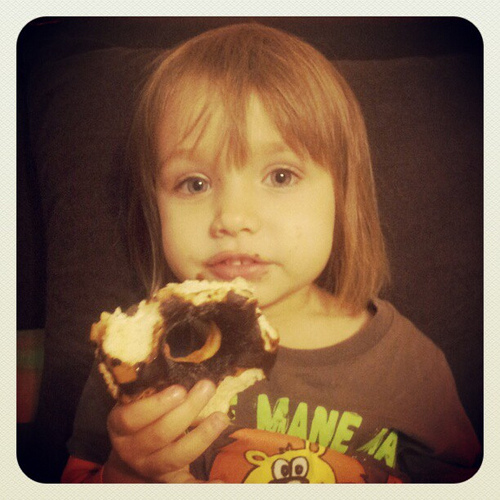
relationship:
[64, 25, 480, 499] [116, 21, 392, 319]
girl with hair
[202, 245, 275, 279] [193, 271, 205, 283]
mouth with crumbs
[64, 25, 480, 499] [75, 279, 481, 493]
girl wearing pullover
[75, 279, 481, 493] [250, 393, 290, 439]
pullover with m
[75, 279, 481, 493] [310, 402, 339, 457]
pullover with n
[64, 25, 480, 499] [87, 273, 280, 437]
girl holding donut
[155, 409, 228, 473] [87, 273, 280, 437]
fingers holding donut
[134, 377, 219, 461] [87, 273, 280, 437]
fingers holding donut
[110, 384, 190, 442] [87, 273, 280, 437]
fingers holding donut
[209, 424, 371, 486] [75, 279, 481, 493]
lion on pullover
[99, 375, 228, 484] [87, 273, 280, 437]
hand holding donut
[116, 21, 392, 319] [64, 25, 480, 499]
hair on girl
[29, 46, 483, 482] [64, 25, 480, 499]
chair behind girl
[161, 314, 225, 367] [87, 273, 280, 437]
center of donut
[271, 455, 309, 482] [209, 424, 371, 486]
eyes of lion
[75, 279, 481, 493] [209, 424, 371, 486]
pullover with lion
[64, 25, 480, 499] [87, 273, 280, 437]
girl eating donut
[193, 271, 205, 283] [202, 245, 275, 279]
crumbs on mouth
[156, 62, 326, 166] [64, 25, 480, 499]
bangs on girl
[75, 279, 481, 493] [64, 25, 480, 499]
pullover of girl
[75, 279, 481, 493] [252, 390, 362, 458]
pullover says mane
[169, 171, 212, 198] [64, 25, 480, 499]
eyes of girl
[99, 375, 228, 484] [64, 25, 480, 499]
hand of girl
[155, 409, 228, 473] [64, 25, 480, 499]
fingers of girl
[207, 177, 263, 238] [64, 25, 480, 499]
nose of girl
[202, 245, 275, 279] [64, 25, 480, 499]
mouth of girl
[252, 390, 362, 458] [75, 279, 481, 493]
mane on pullover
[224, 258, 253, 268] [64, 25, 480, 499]
teeth of girl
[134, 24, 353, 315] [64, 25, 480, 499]
head of girl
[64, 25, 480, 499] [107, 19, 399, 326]
girl has brown hair